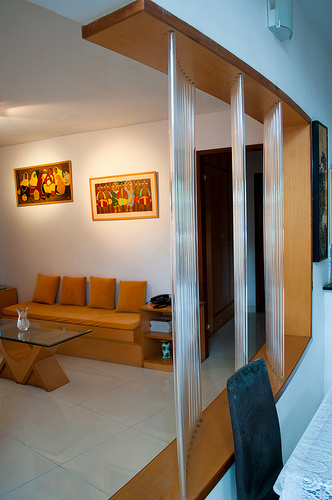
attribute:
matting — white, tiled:
[0, 312, 266, 499]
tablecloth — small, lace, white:
[275, 379, 331, 498]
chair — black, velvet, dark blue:
[229, 358, 282, 500]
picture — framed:
[90, 172, 159, 221]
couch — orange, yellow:
[5, 273, 157, 364]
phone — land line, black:
[152, 292, 172, 310]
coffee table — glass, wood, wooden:
[3, 317, 91, 392]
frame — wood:
[196, 145, 265, 358]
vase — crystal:
[15, 305, 30, 332]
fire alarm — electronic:
[268, 0, 294, 45]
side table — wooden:
[139, 301, 206, 373]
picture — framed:
[12, 159, 75, 209]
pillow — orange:
[116, 280, 148, 315]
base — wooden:
[2, 338, 68, 391]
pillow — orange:
[87, 277, 116, 309]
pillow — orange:
[61, 276, 88, 305]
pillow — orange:
[32, 272, 59, 302]